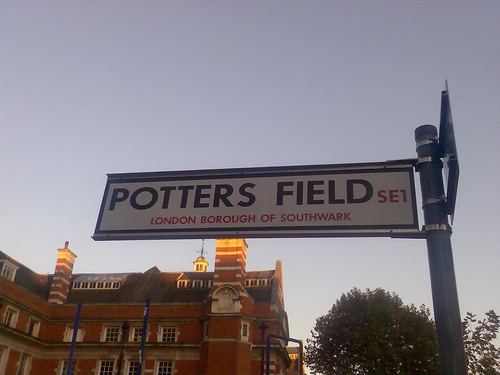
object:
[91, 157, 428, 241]
sign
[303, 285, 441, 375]
tree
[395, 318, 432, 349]
leaves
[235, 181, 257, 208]
letters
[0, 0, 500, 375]
sky